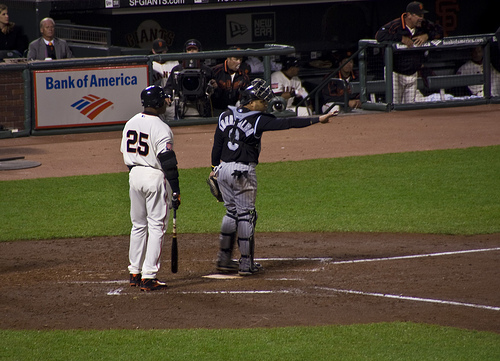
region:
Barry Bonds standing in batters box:
[120, 85, 179, 297]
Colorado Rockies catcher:
[207, 82, 335, 276]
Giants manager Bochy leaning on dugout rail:
[373, 2, 438, 105]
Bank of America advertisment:
[35, 66, 146, 124]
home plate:
[205, 270, 239, 280]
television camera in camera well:
[171, 70, 210, 113]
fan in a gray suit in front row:
[27, 17, 76, 58]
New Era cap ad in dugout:
[227, 13, 276, 43]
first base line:
[314, 282, 499, 312]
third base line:
[330, 243, 499, 267]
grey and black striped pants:
[200, 156, 272, 288]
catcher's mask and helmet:
[231, 74, 278, 114]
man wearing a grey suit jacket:
[24, 16, 78, 67]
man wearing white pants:
[376, 2, 436, 115]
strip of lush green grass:
[0, 143, 499, 248]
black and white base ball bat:
[160, 193, 190, 288]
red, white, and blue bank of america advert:
[20, 60, 153, 140]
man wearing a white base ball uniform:
[99, 83, 184, 298]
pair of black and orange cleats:
[119, 269, 171, 294]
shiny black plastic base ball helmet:
[130, 81, 181, 118]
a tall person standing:
[118, 76, 175, 291]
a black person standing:
[217, 76, 304, 288]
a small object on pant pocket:
[223, 165, 254, 196]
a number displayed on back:
[111, 122, 184, 165]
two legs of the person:
[113, 203, 182, 282]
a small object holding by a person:
[167, 202, 175, 291]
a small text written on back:
[217, 101, 265, 161]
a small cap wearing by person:
[138, 78, 195, 115]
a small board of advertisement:
[21, 54, 192, 141]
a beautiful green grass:
[25, 153, 495, 236]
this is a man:
[128, 91, 174, 290]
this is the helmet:
[139, 85, 174, 110]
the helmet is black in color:
[143, 90, 161, 99]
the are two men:
[133, 86, 284, 256]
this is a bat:
[171, 212, 179, 277]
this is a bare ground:
[286, 237, 450, 309]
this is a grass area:
[332, 161, 429, 202]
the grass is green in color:
[306, 160, 346, 182]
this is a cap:
[406, 5, 421, 7]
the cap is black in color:
[411, 5, 423, 10]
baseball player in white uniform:
[120, 85, 182, 298]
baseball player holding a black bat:
[118, 82, 182, 300]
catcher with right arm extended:
[209, 82, 336, 270]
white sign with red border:
[30, 65, 152, 132]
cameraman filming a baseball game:
[167, 40, 217, 119]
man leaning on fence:
[373, 1, 439, 106]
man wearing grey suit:
[28, 17, 77, 70]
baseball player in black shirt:
[209, 75, 340, 280]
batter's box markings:
[112, 242, 340, 311]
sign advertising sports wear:
[223, 10, 277, 48]